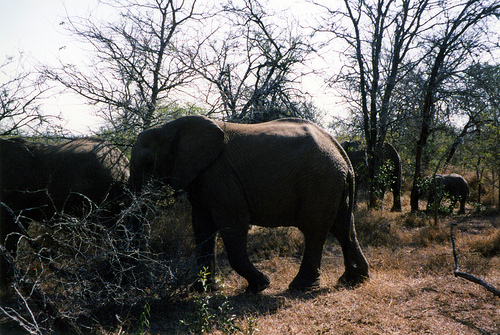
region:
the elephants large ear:
[161, 110, 274, 215]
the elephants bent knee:
[183, 226, 282, 301]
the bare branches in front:
[26, 195, 201, 323]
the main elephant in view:
[104, 117, 424, 309]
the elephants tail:
[326, 152, 389, 259]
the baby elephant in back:
[422, 160, 478, 226]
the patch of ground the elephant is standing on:
[188, 251, 420, 321]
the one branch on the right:
[419, 216, 489, 325]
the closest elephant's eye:
[125, 147, 176, 186]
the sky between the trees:
[25, 22, 435, 123]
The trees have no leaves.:
[68, 8, 214, 65]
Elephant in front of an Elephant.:
[2, 114, 132, 233]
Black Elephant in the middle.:
[120, 106, 374, 303]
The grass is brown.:
[294, 298, 421, 329]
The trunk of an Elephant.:
[386, 142, 412, 224]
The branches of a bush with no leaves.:
[13, 193, 180, 322]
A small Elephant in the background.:
[424, 157, 478, 219]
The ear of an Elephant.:
[155, 107, 228, 193]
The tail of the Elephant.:
[343, 175, 367, 258]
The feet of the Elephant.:
[186, 253, 380, 298]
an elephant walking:
[117, 115, 391, 306]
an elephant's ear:
[164, 95, 219, 242]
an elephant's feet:
[196, 217, 390, 296]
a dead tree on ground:
[445, 218, 497, 302]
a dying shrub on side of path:
[1, 200, 184, 331]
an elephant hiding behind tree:
[413, 169, 484, 215]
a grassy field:
[210, 206, 499, 325]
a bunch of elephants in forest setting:
[0, 58, 499, 325]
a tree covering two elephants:
[355, 0, 499, 205]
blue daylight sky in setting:
[0, 0, 427, 120]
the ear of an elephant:
[160, 107, 228, 199]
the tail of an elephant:
[332, 132, 362, 246]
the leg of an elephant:
[297, 222, 329, 277]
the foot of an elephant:
[284, 265, 327, 292]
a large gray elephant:
[112, 108, 372, 303]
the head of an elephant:
[125, 115, 192, 187]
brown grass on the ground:
[189, 187, 496, 333]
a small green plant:
[136, 261, 257, 333]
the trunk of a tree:
[407, 165, 426, 210]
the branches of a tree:
[40, 0, 227, 121]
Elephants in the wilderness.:
[63, 115, 457, 282]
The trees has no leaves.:
[311, 24, 488, 138]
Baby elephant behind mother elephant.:
[417, 153, 478, 207]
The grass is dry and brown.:
[336, 270, 438, 330]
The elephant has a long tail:
[347, 168, 365, 258]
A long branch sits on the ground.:
[450, 215, 496, 302]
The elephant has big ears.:
[158, 110, 237, 187]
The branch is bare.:
[35, 198, 170, 300]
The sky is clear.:
[71, 13, 496, 155]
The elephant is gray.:
[123, 92, 386, 297]